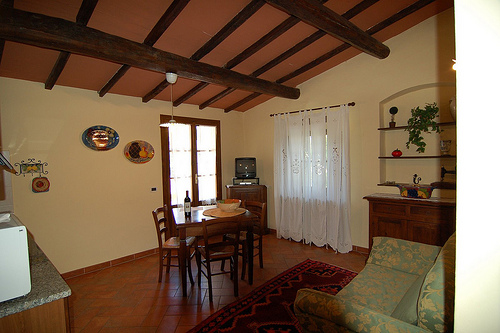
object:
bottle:
[184, 190, 191, 216]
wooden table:
[173, 206, 253, 289]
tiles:
[101, 280, 188, 331]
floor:
[74, 270, 197, 332]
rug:
[182, 257, 357, 331]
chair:
[292, 235, 456, 331]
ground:
[279, 251, 356, 262]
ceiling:
[167, 5, 269, 57]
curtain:
[271, 105, 353, 254]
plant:
[405, 102, 442, 153]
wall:
[74, 101, 313, 231]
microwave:
[1, 207, 35, 300]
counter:
[2, 236, 71, 332]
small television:
[234, 157, 256, 177]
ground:
[79, 273, 277, 327]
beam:
[3, 6, 300, 98]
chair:
[152, 206, 202, 285]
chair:
[224, 200, 266, 280]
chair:
[194, 218, 241, 301]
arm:
[296, 287, 372, 332]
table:
[149, 206, 261, 229]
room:
[0, 16, 450, 333]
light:
[160, 73, 186, 127]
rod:
[269, 102, 355, 117]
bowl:
[216, 199, 242, 212]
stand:
[232, 178, 259, 186]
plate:
[80, 124, 120, 151]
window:
[284, 122, 342, 202]